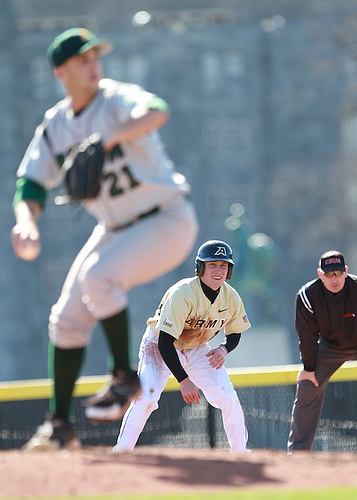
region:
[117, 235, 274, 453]
The runner is on base.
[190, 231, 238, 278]
His helmet is green.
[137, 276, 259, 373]
His shirt is tan.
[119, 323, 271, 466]
His pants are white.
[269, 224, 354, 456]
The umpire is black.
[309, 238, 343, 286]
The hat is black.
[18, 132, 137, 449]
He is throwing a ball.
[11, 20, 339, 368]
They are playing baseball.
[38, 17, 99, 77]
He is wearing a green hat.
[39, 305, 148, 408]
His socks are green.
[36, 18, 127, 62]
a blurry green baseball cap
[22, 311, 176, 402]
green socks on a baseball player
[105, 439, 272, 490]
the shadow of a ball player on the ground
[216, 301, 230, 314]
the Nike swoosh symbol on a baseball uniform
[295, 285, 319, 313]
two white stripes on the shoulder of the coach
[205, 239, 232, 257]
a white block letter A on the front of a player's helmet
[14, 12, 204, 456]
a baseball player preparing to pitch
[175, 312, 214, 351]
an area of dirt on the front of a uniform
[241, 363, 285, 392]
the yellow band at the top of a chain link fence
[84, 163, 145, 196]
the number 21 on the pitcher's shirt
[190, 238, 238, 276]
the helmet is blue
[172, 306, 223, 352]
the shirt is brown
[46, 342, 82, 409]
the socks are green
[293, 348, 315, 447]
the pants are grey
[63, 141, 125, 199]
the glove is black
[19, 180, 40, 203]
the shirt is green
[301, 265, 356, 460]
the man has sunglasses on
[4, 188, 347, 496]
the game is baseball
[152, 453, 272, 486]
shadow is on the ground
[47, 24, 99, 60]
the cap is green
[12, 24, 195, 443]
a person in the picture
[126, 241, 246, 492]
a person in the picture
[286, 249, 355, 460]
a person in the picture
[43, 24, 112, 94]
the man has a cap on his head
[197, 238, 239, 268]
the man has a cap on his head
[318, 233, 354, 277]
the man has a cap on his head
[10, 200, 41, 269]
the man is about to throw a ball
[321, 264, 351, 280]
the man is wearing spectacles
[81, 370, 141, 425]
that is a shoe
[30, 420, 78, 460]
that is a shoe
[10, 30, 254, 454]
people are playing baseball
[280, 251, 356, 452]
umpire wearing all black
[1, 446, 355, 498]
pitcher is standing on mound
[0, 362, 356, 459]
black fence in background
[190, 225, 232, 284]
player in back has helmet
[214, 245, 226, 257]
helmet has an A on it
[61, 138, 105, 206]
pitcher has black mit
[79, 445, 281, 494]
pitcher is casting shadow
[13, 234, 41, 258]
pitcher is holding baseball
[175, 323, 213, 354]
player is covered in dirt